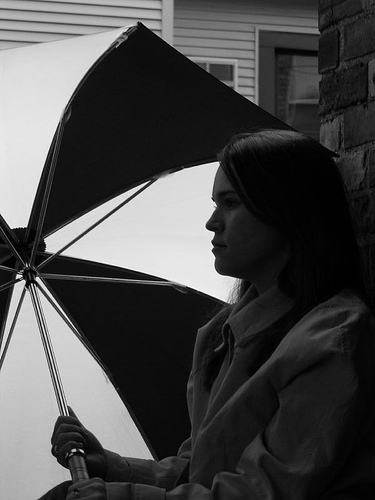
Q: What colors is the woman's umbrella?
A: Black and white.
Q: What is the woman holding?
A: An umbrella.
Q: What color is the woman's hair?
A: Black.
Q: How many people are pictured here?
A: One.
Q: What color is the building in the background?
A: White.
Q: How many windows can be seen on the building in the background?
A: Two.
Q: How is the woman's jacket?
A: Wrinkled.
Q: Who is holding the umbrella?
A: A woman.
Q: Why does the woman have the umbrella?
A: To protect from rain.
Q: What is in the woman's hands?
A: Umbrella.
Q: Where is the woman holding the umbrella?
A: By the handle.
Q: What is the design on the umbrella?
A: Striped.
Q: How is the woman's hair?
A: Straight.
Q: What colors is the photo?
A: Black and white.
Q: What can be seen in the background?
A: The tiles of a house.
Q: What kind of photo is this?
A: Black and white.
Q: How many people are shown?
A: One.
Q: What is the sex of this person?
A: Female.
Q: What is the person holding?
A: An umbrella.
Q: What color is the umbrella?
A: Black and white.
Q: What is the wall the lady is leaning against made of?
A: Brick.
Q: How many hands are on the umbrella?
A: Two.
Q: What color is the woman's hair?
A: Brunette.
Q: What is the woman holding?
A: An umbrella.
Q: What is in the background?
A: A house.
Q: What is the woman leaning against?
A: A brick wall.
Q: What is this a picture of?
A: A young woman.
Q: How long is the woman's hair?
A: Shoulder length.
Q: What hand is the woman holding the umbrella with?
A: Right hand.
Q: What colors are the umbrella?
A: Black and white.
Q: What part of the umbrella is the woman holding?
A: The handle.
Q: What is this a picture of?
A: A woman holding an umbrella.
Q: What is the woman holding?
A: Umbrella.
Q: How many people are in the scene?
A: 1.